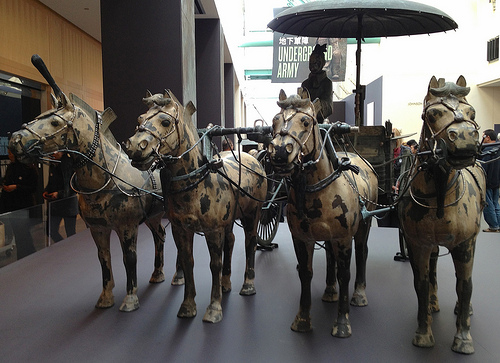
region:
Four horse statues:
[2, 58, 485, 361]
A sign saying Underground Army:
[245, 9, 355, 86]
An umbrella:
[256, 0, 456, 137]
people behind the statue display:
[291, 80, 496, 290]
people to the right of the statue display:
[0, 76, 160, 266]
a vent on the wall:
[457, 28, 498, 90]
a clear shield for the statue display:
[2, 185, 141, 280]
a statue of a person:
[260, 38, 352, 133]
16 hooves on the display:
[76, 259, 492, 356]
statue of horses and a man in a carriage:
[3, 67, 498, 357]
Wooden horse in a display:
[397, 77, 499, 284]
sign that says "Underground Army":
[272, 39, 347, 81]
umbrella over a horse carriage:
[269, 7, 461, 48]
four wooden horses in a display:
[24, 55, 499, 307]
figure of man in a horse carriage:
[285, 47, 346, 123]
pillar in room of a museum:
[89, 17, 207, 89]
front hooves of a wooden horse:
[92, 284, 147, 315]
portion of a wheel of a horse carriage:
[252, 198, 285, 249]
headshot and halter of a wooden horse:
[123, 88, 224, 186]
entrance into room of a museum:
[476, 77, 499, 117]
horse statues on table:
[2, 78, 489, 338]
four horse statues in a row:
[39, 140, 469, 315]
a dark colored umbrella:
[271, 5, 441, 109]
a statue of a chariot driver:
[281, 47, 331, 127]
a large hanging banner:
[270, 12, 361, 94]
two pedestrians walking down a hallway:
[1, 150, 87, 233]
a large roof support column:
[97, 5, 197, 208]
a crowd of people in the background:
[228, 125, 498, 212]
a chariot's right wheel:
[241, 147, 284, 249]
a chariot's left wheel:
[388, 151, 427, 258]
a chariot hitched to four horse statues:
[232, 100, 414, 260]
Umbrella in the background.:
[275, 2, 474, 50]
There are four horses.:
[16, 100, 498, 321]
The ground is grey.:
[36, 301, 116, 361]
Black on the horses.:
[200, 173, 235, 219]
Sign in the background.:
[275, 9, 352, 86]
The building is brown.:
[18, 15, 110, 80]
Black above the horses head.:
[30, 51, 85, 103]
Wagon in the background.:
[220, 120, 395, 215]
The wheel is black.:
[241, 145, 299, 250]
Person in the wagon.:
[295, 35, 345, 119]